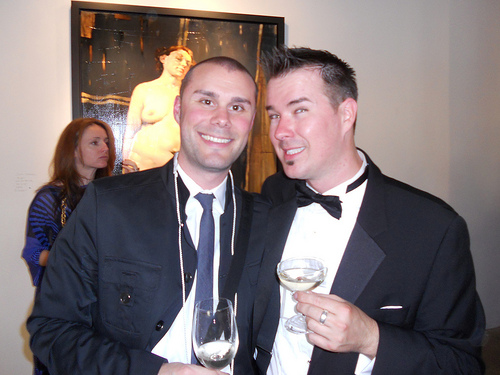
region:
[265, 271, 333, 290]
clear liquid in glass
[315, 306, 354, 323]
silver wedding band on man's hand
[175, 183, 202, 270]
white string around man's neck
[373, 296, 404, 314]
edge of white handkerchief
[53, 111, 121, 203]
long ginger hair on woman's head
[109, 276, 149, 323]
black buttons on jacket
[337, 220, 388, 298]
lapel on blue jacket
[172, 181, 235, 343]
blue tie around man's neck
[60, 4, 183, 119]
risque picture on wall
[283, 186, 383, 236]
black bow tie around man's neck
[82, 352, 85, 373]
Nude framed picture on wall.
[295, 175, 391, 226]
Man's formal bow tie.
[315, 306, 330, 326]
Silver ring worn on middle finger.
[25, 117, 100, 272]
Lady wearing a blue and black outfit.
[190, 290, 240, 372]
Almost empty wine glass.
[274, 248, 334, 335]
Martini drink with olive.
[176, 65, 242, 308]
Man wearing a blue tie with white shirt.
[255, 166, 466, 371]
Men's formal suit.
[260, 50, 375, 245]
Men's white formal shirt.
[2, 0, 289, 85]
Brown frame for nude picture on wall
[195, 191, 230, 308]
a long blue tie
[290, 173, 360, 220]
a black bow tie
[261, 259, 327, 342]
a small wine glass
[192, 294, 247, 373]
a large wine glass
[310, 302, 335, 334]
a silver band on a middle finger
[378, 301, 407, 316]
a white handkerchief in a man's jacket pocket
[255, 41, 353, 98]
a man's spiked hair style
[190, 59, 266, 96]
a man's cropped hair style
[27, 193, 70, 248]
a blue and black striped shirt on a woman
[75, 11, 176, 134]
a nude painting on the far wall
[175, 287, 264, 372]
The man has a drink in his cup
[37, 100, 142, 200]
The woman's hair is down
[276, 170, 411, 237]
The man has a bow tie on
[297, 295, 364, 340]
This man has a ring on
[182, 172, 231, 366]
The man has a tie on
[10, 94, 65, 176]
The wall is light colored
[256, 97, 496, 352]
The man has a tux on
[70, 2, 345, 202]
There is a painting behind the people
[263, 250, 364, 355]
The man has a drink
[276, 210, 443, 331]
The man's shirt is white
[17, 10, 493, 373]
people at an art gallery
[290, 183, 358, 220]
bow tie on a man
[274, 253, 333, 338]
champagne in a glass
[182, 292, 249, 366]
wine in a glass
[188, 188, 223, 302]
blue tie on a man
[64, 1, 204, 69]
painting on a wall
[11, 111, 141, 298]
woman next to painting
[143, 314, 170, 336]
button on a jacket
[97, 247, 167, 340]
pocket on a jacket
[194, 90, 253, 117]
eyes of a man